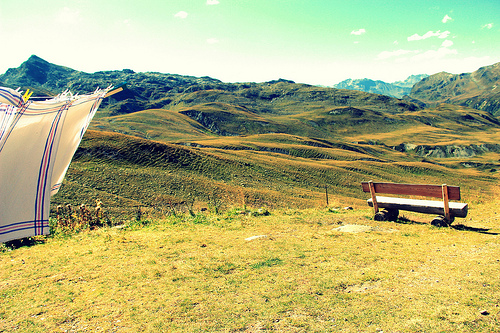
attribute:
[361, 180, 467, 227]
bench — wood, wooden, long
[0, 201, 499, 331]
field — grassy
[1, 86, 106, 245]
blanket — red, white, blue, hanging, blowing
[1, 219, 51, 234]
stripes — horizontal, pink, blue, red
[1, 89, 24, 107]
stripes — blue, pink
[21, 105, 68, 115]
stripes — blue, pink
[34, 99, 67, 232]
stripes — red, blue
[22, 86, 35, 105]
clothespin — yellow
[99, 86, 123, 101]
clothespin — brown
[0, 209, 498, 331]
grass — green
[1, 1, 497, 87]
sky — white, green, cloudy, beautiful, overhead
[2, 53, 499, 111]
mountains — grassy, mossy, tall, jagged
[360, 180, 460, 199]
back rest — wooden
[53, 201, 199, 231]
fence — small, chainlink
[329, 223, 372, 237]
spot — white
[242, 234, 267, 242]
spot — white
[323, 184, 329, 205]
fence post — black, small